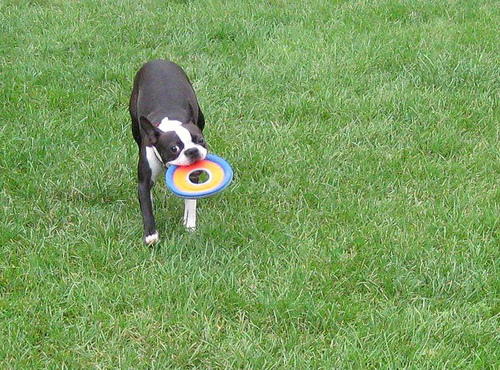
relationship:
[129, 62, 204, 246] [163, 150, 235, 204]
dog carrying frisbee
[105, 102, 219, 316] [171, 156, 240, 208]
dog holding frisbee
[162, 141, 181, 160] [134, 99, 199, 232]
eye of  a dog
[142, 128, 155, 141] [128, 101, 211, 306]
ear of a dog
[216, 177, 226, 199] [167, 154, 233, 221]
blue and orange frisbee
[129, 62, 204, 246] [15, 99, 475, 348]
dog in a field of grass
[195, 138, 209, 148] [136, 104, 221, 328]
eye of a dog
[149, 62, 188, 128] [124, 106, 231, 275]
back of a dog